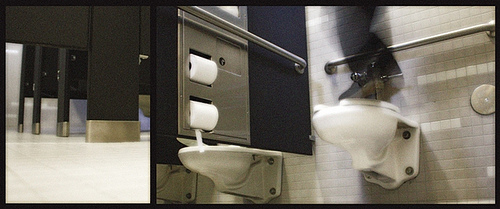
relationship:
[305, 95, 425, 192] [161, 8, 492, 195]
toilet attached to wall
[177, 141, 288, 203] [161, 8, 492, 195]
toilet attached to wall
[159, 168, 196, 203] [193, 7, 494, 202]
toilet attached to wall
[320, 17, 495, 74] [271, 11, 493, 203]
bar attached to wall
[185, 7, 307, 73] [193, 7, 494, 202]
handle attached to wall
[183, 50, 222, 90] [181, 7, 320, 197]
paper in stall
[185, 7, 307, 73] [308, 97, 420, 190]
handle next to toilet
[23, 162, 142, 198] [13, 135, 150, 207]
tile on floor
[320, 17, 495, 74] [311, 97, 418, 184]
bar on back of toilet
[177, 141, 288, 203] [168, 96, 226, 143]
toilet under paper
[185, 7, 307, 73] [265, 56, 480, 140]
handle near toilet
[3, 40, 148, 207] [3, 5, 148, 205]
tile in room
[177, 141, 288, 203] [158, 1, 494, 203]
toilet in photo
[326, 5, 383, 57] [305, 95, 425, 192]
shadow above toilet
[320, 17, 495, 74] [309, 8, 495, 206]
bar on wall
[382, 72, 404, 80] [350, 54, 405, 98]
lever with pipes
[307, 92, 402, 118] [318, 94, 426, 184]
lid of toilet